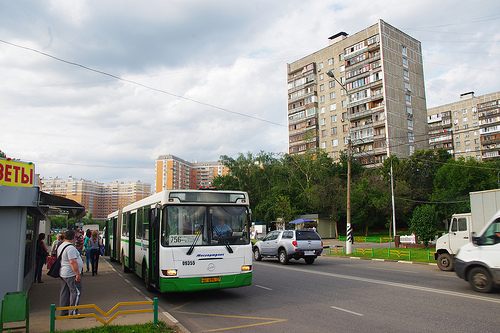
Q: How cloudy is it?
A: Very cloudy.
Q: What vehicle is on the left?
A: Bus.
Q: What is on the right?
A: Building.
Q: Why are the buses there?
A: Picking up people.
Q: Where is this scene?
A: Street corner.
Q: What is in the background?
A: Trees.